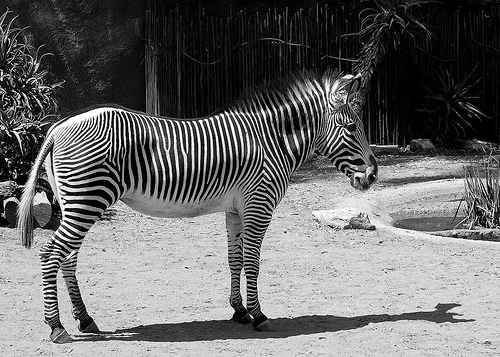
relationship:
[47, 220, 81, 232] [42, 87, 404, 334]
stripe on zebra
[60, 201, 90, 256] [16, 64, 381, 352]
stripe on zebra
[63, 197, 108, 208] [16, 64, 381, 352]
black stripe on zebra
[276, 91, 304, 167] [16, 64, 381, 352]
stripe on zebra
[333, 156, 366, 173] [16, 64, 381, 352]
stripe on zebra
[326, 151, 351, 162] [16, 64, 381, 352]
stripe on zebra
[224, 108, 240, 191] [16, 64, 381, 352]
stripe on zebra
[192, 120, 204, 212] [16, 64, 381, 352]
stripe on zebra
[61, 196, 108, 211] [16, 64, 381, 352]
stripe on zebra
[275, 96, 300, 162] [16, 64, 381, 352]
stripe on zebra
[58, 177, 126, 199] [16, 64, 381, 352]
stripe on zebra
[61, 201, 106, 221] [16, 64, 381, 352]
stripe on zebra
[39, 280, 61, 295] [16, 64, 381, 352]
stripe on zebra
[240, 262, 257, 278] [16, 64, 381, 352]
stripe on zebra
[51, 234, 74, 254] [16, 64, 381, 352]
stripe on zebra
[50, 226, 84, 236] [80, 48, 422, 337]
stripe on zebra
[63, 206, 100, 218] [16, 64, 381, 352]
black stripe on zebra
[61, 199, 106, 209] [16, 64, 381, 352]
black stripe on zebra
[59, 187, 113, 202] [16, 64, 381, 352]
black stripe on zebra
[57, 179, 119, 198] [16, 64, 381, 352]
black stripe on zebra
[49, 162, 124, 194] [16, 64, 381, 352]
black stripe on zebra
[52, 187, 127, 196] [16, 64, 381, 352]
stripe on zebra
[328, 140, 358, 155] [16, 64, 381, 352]
stripe on zebra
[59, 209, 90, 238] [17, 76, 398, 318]
stripe on zebra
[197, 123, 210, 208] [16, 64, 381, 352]
stripe on zebra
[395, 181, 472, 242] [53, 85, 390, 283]
water for zebra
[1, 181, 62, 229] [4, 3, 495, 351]
wood in habitat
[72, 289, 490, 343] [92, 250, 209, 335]
shadow in dirt